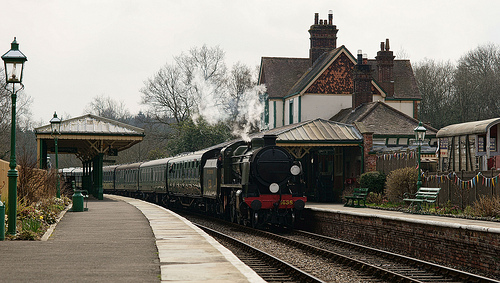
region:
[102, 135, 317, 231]
Black train on train tracks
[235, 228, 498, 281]
Metal train tracks on ground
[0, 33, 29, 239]
Street lamp on sidewalk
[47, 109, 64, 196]
Street lamp on sidewalk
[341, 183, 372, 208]
Green colored bench on sidewalk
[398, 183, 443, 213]
Green colored bench on sidewalk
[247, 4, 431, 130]
White building with grey roof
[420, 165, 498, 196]
Multi-colored flags on fence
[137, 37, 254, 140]
Large tree in background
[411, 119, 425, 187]
Street lamp next to bench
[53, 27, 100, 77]
Part of the sky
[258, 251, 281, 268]
Part of the train tracks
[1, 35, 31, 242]
A light on the sidewalk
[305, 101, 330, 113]
Part of the building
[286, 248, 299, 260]
Part of the gravel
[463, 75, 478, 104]
Part of the trees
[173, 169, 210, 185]
Part of the train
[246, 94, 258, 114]
Part of the smoke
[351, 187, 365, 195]
Part of the green bench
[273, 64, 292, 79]
Part of the roof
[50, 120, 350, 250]
this is a train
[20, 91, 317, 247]
this is a passenger train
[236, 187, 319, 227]
bottom of the train is red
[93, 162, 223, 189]
a row of windows on train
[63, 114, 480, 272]
train is on the tracks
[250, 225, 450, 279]
a set of train tracks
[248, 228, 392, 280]
gravel on the tracks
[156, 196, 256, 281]
white line on platform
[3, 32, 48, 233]
a green light post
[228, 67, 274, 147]
smoke from the train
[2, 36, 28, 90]
lamp on green pole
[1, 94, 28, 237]
green pole at station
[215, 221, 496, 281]
train tracks on the ground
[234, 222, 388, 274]
gravel on the train tracks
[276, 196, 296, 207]
numbers printed on train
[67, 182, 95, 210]
green trash can at station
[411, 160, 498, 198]
multi colored flags on wall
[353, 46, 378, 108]
chimney on the roof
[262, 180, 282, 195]
head light on the train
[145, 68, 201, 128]
bare trees in background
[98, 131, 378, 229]
a train is on the tracks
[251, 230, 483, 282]
train tracks are set here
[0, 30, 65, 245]
two lamps on the side walk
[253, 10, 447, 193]
a structure is to the right of the train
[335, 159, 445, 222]
two benches sit on the side walk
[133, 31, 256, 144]
a tree is near the building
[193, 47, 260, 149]
steam from the engine rises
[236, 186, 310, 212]
a small portion of the train is red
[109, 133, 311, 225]
the train is black in color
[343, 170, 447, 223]
the benches are green in color